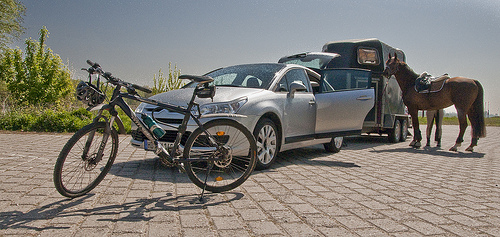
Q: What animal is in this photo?
A: Horse.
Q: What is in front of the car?
A: A bicycle.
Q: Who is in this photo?
A: Nobody.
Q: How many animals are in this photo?
A: One.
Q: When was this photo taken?
A: Daytime.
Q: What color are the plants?
A: Green.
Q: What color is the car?
A: Silver.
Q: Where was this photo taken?
A: In a parking lot.